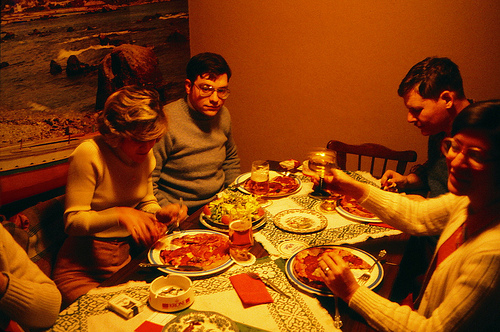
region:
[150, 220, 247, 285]
Pizza on a white plate.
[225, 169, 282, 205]
Glass next to a plate.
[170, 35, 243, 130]
Man with brunette hair and glasses.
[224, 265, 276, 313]
Red napkin on the table.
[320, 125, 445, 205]
Empty wooden chair at a table.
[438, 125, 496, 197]
Woman with glasses.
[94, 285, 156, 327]
A package of cigarettes.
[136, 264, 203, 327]
Ashtray next to the cigarettes.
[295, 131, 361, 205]
Woman holding a wine glass.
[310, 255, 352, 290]
Woman wearing a wedding band.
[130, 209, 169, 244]
woman is holding a slice of pizza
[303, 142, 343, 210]
woman is holding up her glass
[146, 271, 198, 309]
white ash tray is next to woman's plate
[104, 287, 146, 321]
pack of cigarettes is next to ash tray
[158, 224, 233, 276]
plate is holding a small pizza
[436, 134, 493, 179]
woman is wearing glasses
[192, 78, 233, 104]
man is wearing glasses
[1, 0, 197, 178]
painting is on left wall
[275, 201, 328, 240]
empty plate in middle of table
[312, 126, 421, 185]
chair at end of table is empty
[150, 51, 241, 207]
a man is wearing a gray sweater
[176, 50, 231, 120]
a man has dark hair and glasses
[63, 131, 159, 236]
the lady is wearing a long sleeve sweater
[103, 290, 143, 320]
an open pack of cigarettes is on the table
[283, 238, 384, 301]
a fork is on the side of a plate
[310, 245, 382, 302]
a lady's wrist is on the plate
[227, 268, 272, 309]
a red napkin is in the middle of the table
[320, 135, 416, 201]
a spindled chair is at the head of the table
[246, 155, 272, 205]
a glass of beer is half full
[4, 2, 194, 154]
a picture is on the wall of the room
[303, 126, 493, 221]
a lady holding a glass up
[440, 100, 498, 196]
the lady is wearing glasses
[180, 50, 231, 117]
the man is wearing glasses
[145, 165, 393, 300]
five plates of food are on the table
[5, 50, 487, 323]
five people are sitting at the table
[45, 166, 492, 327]
two table clothes cover the table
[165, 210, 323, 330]
two small empty plates on the table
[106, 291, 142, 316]
a pack of cigarettes are on the table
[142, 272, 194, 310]
an ashtray with red lettering on the side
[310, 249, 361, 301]
a hand with a wedding ring on it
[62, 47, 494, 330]
Family eating Italian dinner.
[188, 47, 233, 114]
Man wearing glasses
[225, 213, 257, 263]
Woman's drinking glass appears to be beer.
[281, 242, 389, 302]
Woman's dinner is pizza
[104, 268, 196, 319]
Cigarette pack and ashtray on dinner table.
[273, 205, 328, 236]
Empty plate on table.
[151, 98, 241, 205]
Man wearing brown sweater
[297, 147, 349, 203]
Woman getting ready to toast.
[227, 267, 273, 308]
Napkin on dinner table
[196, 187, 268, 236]
Large Italian salad, untouched.